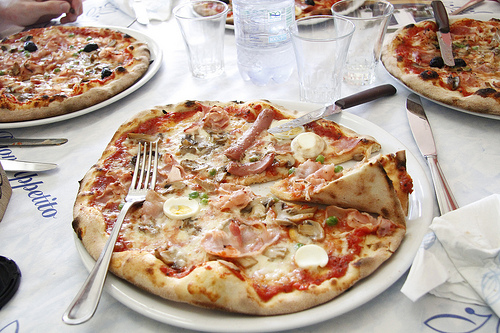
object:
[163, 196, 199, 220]
egg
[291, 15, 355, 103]
glass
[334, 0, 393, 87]
glass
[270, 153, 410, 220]
slice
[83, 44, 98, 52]
olive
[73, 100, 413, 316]
pizza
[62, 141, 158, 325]
fork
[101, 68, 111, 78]
olive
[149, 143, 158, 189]
prong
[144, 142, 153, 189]
prong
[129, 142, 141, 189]
prong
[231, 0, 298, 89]
bottle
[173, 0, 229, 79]
glass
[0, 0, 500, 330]
table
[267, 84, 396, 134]
knife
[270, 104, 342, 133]
blade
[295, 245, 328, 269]
mushroom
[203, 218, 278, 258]
bacon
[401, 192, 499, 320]
napkin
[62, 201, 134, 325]
handle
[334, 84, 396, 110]
handle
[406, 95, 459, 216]
knife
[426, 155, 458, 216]
handle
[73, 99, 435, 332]
dish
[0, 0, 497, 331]
cloth